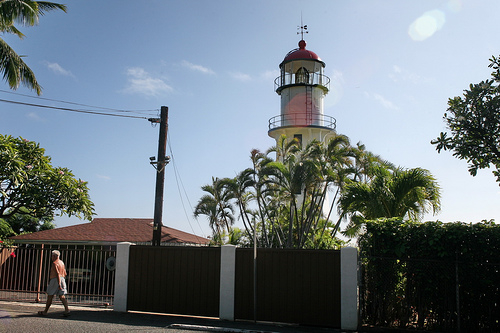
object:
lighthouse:
[267, 39, 337, 249]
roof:
[278, 39, 326, 66]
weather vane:
[295, 12, 310, 40]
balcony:
[273, 71, 330, 96]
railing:
[268, 112, 338, 131]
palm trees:
[289, 154, 298, 249]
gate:
[112, 240, 359, 331]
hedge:
[357, 216, 500, 332]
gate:
[0, 238, 118, 311]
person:
[36, 249, 73, 318]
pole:
[151, 105, 169, 247]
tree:
[0, 134, 99, 243]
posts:
[113, 240, 134, 312]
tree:
[335, 165, 444, 238]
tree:
[0, 0, 70, 99]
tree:
[430, 51, 499, 184]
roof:
[8, 217, 213, 244]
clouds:
[146, 87, 150, 88]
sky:
[1, 0, 500, 243]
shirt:
[49, 259, 68, 279]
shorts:
[45, 276, 68, 296]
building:
[7, 217, 214, 308]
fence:
[112, 240, 500, 332]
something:
[0, 244, 20, 268]